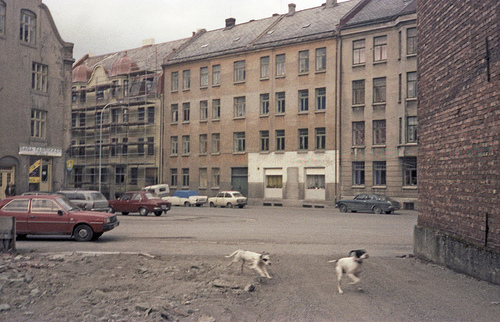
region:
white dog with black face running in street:
[325, 241, 373, 297]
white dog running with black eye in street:
[224, 245, 274, 280]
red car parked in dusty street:
[0, 191, 120, 241]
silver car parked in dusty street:
[60, 183, 115, 213]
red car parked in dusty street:
[110, 187, 174, 217]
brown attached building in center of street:
[160, 0, 340, 210]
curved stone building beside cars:
[0, 0, 87, 203]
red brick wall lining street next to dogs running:
[412, 0, 497, 295]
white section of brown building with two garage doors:
[247, 146, 340, 200]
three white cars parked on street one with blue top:
[140, 182, 250, 207]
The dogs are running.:
[216, 248, 386, 318]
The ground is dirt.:
[134, 196, 464, 316]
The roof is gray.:
[89, 4, 400, 71]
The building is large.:
[72, 25, 439, 197]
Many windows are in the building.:
[80, 37, 412, 212]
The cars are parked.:
[8, 169, 250, 237]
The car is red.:
[9, 189, 116, 247]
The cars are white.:
[163, 184, 246, 218]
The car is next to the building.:
[332, 186, 397, 228]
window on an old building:
[166, 65, 180, 96]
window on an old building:
[183, 65, 194, 92]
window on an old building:
[191, 61, 210, 88]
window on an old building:
[209, 61, 226, 86]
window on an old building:
[227, 55, 252, 89]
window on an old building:
[251, 53, 271, 83]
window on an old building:
[271, 48, 293, 85]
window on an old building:
[291, 47, 311, 81]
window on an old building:
[312, 45, 329, 77]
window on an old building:
[308, 124, 326, 149]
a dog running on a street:
[325, 247, 371, 296]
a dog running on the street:
[225, 244, 274, 280]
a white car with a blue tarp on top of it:
[161, 186, 208, 208]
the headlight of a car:
[103, 214, 116, 227]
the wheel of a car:
[71, 220, 98, 242]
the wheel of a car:
[136, 205, 149, 218]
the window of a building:
[29, 59, 54, 99]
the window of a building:
[26, 105, 50, 141]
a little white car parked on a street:
[204, 186, 248, 209]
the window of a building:
[347, 36, 370, 69]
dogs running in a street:
[222, 240, 374, 296]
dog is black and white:
[328, 239, 375, 294]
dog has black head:
[346, 244, 373, 264]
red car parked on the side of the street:
[4, 186, 121, 246]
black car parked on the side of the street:
[334, 190, 401, 216]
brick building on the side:
[410, 0, 498, 290]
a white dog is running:
[222, 245, 280, 284]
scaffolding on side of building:
[71, 52, 156, 199]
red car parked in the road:
[109, 185, 175, 218]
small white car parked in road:
[204, 186, 249, 212]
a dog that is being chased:
[323, 245, 378, 298]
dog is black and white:
[324, 245, 374, 292]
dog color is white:
[225, 247, 280, 282]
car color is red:
[0, 194, 121, 245]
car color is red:
[105, 187, 175, 219]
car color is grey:
[51, 185, 112, 212]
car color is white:
[208, 189, 244, 207]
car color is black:
[336, 190, 403, 216]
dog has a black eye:
[261, 256, 268, 262]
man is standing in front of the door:
[1, 164, 18, 199]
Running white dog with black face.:
[326, 249, 368, 294]